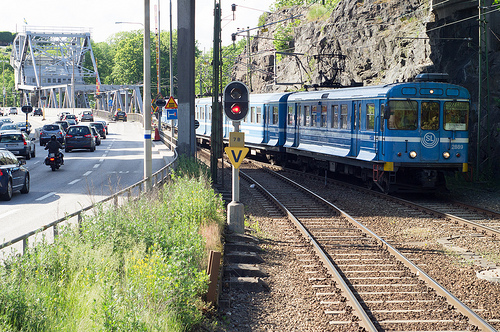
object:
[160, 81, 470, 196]
train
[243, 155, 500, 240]
tracks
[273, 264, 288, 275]
gravel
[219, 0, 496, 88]
power cables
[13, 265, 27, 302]
weeds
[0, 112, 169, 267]
road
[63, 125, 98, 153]
cars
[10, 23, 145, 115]
bridge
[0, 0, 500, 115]
background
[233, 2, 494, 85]
rock face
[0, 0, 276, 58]
sky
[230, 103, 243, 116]
light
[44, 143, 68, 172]
motorcycle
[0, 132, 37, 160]
cars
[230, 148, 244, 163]
v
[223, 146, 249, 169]
sign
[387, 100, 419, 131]
windshield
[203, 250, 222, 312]
post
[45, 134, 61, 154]
man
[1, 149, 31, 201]
car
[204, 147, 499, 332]
tracks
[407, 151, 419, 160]
lights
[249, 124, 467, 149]
stripe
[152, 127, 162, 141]
caution cone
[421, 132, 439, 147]
sl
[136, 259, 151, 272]
flowers